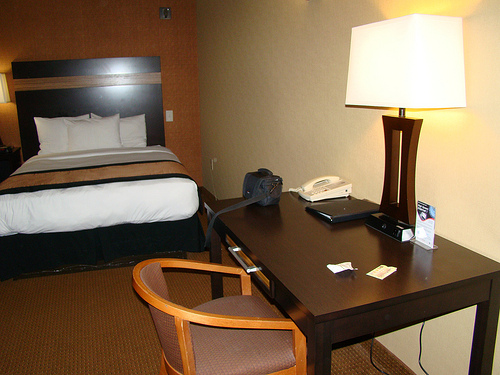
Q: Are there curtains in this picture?
A: No, there are no curtains.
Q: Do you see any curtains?
A: No, there are no curtains.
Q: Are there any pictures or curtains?
A: No, there are no curtains or pictures.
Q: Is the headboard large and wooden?
A: Yes, the headboard is large and wooden.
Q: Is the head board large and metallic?
A: No, the head board is large but wooden.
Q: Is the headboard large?
A: Yes, the headboard is large.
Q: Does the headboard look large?
A: Yes, the headboard is large.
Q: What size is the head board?
A: The head board is large.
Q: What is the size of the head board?
A: The head board is large.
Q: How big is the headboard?
A: The headboard is large.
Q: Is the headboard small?
A: No, the headboard is large.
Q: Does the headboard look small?
A: No, the headboard is large.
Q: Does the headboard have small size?
A: No, the headboard is large.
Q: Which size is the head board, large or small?
A: The head board is large.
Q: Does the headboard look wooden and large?
A: Yes, the headboard is wooden and large.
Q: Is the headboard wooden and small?
A: No, the headboard is wooden but large.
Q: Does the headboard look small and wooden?
A: No, the headboard is wooden but large.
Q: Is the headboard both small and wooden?
A: No, the headboard is wooden but large.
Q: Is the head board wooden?
A: Yes, the head board is wooden.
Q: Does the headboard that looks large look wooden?
A: Yes, the headboard is wooden.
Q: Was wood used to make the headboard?
A: Yes, the headboard is made of wood.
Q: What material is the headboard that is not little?
A: The headboard is made of wood.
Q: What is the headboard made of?
A: The headboard is made of wood.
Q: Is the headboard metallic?
A: No, the headboard is wooden.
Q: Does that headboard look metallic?
A: No, the headboard is wooden.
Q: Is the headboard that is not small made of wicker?
A: No, the headboard is made of wood.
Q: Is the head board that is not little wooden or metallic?
A: The headboard is wooden.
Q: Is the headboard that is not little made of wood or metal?
A: The headboard is made of wood.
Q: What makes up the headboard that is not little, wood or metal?
A: The headboard is made of wood.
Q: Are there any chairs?
A: Yes, there is a chair.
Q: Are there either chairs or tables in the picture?
A: Yes, there is a chair.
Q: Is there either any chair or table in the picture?
A: Yes, there is a chair.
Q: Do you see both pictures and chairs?
A: No, there is a chair but no pictures.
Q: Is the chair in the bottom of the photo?
A: Yes, the chair is in the bottom of the image.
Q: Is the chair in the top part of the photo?
A: No, the chair is in the bottom of the image.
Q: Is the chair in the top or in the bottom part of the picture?
A: The chair is in the bottom of the image.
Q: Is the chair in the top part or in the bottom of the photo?
A: The chair is in the bottom of the image.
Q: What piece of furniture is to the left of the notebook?
A: The piece of furniture is a chair.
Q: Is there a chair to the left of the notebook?
A: Yes, there is a chair to the left of the notebook.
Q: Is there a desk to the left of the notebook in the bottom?
A: No, there is a chair to the left of the notebook.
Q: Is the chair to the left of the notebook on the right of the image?
A: Yes, the chair is to the left of the notebook.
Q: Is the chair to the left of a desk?
A: No, the chair is to the left of the notebook.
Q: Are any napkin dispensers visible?
A: No, there are no napkin dispensers.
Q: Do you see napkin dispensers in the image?
A: No, there are no napkin dispensers.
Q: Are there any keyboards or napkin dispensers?
A: No, there are no napkin dispensers or keyboards.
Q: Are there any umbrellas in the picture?
A: No, there are no umbrellas.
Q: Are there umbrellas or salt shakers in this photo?
A: No, there are no umbrellas or salt shakers.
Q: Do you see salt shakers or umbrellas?
A: No, there are no umbrellas or salt shakers.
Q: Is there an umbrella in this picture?
A: No, there are no umbrellas.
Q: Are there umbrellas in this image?
A: No, there are no umbrellas.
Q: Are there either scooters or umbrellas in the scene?
A: No, there are no umbrellas or scooters.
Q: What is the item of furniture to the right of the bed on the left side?
A: The piece of furniture is a drawer.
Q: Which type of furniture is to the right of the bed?
A: The piece of furniture is a drawer.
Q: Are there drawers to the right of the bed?
A: Yes, there is a drawer to the right of the bed.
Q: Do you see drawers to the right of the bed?
A: Yes, there is a drawer to the right of the bed.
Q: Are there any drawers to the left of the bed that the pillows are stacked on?
A: No, the drawer is to the right of the bed.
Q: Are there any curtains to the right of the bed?
A: No, there is a drawer to the right of the bed.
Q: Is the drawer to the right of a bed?
A: Yes, the drawer is to the right of a bed.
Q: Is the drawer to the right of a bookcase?
A: No, the drawer is to the right of a bed.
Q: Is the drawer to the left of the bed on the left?
A: No, the drawer is to the right of the bed.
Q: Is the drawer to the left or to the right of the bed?
A: The drawer is to the right of the bed.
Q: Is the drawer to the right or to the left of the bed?
A: The drawer is to the right of the bed.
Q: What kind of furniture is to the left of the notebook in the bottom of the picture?
A: The piece of furniture is a drawer.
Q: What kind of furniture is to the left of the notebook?
A: The piece of furniture is a drawer.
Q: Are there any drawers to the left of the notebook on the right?
A: Yes, there is a drawer to the left of the notebook.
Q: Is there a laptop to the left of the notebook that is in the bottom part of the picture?
A: No, there is a drawer to the left of the notebook.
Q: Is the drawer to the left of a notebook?
A: Yes, the drawer is to the left of a notebook.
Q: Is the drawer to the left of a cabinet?
A: No, the drawer is to the left of a notebook.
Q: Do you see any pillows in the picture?
A: Yes, there are pillows.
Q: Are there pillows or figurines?
A: Yes, there are pillows.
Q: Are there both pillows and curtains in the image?
A: No, there are pillows but no curtains.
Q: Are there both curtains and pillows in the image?
A: No, there are pillows but no curtains.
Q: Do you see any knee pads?
A: No, there are no knee pads.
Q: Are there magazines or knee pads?
A: No, there are no knee pads or magazines.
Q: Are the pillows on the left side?
A: Yes, the pillows are on the left of the image.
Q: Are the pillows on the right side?
A: No, the pillows are on the left of the image.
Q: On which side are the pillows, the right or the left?
A: The pillows are on the left of the image.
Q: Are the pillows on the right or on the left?
A: The pillows are on the left of the image.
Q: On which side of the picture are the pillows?
A: The pillows are on the left of the image.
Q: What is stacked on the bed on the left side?
A: The pillows are stacked on the bed.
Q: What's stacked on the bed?
A: The pillows are stacked on the bed.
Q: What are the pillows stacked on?
A: The pillows are stacked on the bed.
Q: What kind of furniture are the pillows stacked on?
A: The pillows are stacked on the bed.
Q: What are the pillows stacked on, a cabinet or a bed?
A: The pillows are stacked on a bed.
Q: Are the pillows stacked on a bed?
A: Yes, the pillows are stacked on a bed.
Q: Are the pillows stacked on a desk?
A: No, the pillows are stacked on a bed.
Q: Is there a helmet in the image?
A: No, there are no helmets.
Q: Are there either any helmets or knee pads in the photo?
A: No, there are no helmets or knee pads.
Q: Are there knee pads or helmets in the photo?
A: No, there are no helmets or knee pads.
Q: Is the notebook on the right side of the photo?
A: Yes, the notebook is on the right of the image.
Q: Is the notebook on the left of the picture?
A: No, the notebook is on the right of the image.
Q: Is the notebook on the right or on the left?
A: The notebook is on the right of the image.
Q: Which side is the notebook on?
A: The notebook is on the right of the image.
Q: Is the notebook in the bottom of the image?
A: Yes, the notebook is in the bottom of the image.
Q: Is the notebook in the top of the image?
A: No, the notebook is in the bottom of the image.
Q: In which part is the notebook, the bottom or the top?
A: The notebook is in the bottom of the image.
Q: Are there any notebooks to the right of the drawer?
A: Yes, there is a notebook to the right of the drawer.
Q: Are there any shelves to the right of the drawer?
A: No, there is a notebook to the right of the drawer.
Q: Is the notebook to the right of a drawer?
A: Yes, the notebook is to the right of a drawer.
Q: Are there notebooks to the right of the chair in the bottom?
A: Yes, there is a notebook to the right of the chair.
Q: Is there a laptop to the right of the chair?
A: No, there is a notebook to the right of the chair.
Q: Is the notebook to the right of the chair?
A: Yes, the notebook is to the right of the chair.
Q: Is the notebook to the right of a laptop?
A: No, the notebook is to the right of the chair.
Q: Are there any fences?
A: No, there are no fences.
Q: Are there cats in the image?
A: No, there are no cats.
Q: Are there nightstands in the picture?
A: Yes, there is a nightstand.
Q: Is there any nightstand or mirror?
A: Yes, there is a nightstand.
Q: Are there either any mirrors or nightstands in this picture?
A: Yes, there is a nightstand.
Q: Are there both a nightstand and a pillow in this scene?
A: Yes, there are both a nightstand and a pillow.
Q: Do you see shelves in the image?
A: No, there are no shelves.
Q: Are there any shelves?
A: No, there are no shelves.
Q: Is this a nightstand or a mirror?
A: This is a nightstand.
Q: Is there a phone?
A: Yes, there is a phone.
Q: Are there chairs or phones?
A: Yes, there is a phone.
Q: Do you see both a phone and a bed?
A: Yes, there are both a phone and a bed.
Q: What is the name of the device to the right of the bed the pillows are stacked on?
A: The device is a phone.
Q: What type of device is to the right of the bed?
A: The device is a phone.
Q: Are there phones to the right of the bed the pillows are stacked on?
A: Yes, there is a phone to the right of the bed.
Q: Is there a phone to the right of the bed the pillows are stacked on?
A: Yes, there is a phone to the right of the bed.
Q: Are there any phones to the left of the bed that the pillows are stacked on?
A: No, the phone is to the right of the bed.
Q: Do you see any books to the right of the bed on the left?
A: No, there is a phone to the right of the bed.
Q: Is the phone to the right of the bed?
A: Yes, the phone is to the right of the bed.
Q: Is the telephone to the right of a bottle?
A: No, the telephone is to the right of the bed.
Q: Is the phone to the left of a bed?
A: No, the phone is to the right of a bed.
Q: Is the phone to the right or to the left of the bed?
A: The phone is to the right of the bed.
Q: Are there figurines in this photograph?
A: No, there are no figurines.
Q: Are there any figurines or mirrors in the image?
A: No, there are no figurines or mirrors.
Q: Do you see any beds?
A: Yes, there is a bed.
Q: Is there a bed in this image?
A: Yes, there is a bed.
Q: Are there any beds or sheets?
A: Yes, there is a bed.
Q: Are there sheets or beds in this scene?
A: Yes, there is a bed.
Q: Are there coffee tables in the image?
A: No, there are no coffee tables.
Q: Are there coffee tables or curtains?
A: No, there are no coffee tables or curtains.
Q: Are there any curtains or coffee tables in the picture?
A: No, there are no coffee tables or curtains.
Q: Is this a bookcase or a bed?
A: This is a bed.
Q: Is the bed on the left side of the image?
A: Yes, the bed is on the left of the image.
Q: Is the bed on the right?
A: No, the bed is on the left of the image.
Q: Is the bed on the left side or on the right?
A: The bed is on the left of the image.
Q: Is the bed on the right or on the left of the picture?
A: The bed is on the left of the image.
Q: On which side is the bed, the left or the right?
A: The bed is on the left of the image.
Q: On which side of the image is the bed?
A: The bed is on the left of the image.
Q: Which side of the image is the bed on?
A: The bed is on the left of the image.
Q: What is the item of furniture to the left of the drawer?
A: The piece of furniture is a bed.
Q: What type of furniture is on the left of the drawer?
A: The piece of furniture is a bed.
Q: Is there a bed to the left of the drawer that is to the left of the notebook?
A: Yes, there is a bed to the left of the drawer.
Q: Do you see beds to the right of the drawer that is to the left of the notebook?
A: No, the bed is to the left of the drawer.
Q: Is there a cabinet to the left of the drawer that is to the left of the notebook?
A: No, there is a bed to the left of the drawer.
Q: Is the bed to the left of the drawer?
A: Yes, the bed is to the left of the drawer.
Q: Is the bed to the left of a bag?
A: No, the bed is to the left of the drawer.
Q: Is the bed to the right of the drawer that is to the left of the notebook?
A: No, the bed is to the left of the drawer.